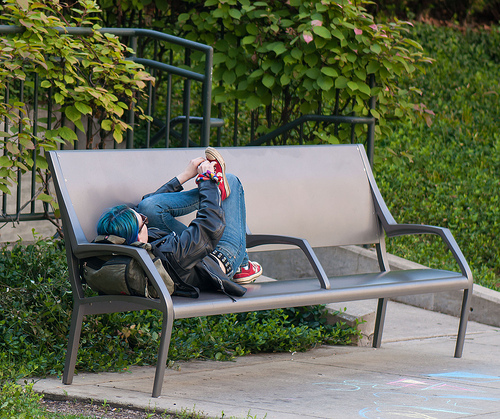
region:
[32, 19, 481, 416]
picture taken outside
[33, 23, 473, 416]
picture taken during the day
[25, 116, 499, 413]
a woman is laying on a bench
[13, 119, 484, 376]
the bench is on the sidewalk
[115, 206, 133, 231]
the woman's hair is blue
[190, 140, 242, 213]
the person is tying her shoes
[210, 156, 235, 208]
the woman wears red shoes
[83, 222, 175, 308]
the woman is laying on a backpack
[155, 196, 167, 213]
the woman wears jeans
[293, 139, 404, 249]
the bench is made of metal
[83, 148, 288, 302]
a girl lying on a metal bench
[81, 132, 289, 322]
this woman has blue hair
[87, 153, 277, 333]
her hair is dyed blue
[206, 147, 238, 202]
red Converse brand sneakers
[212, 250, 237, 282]
a black belt with a lot of holes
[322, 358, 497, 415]
colorful chalk on the ground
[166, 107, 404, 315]
there is a staircase behind the bench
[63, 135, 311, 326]
she is resting her head on her bag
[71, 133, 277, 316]
she is wearing a black leather jacket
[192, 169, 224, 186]
a brightly colored bracelet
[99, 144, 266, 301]
a girl lying on the bench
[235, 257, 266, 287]
the red sneaker on the bench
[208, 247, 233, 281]
the black belt with metal holes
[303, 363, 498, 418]
chalk drawings on the ground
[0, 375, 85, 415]
grass in the dirt patch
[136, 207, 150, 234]
glasses on the face of the women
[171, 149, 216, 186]
the girl ties her shoes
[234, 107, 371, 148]
the hand rail for the stairway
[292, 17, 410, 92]
pink tips on the green leaves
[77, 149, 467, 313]
a person laying on a bench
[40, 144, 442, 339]
a silver bench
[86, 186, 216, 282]
a person with blue and black hair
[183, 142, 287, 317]
red and white converse sneakers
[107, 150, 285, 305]
a person wearing blue jeans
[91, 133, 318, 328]
a person wearing converse sneakers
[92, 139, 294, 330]
a person wearing red and white converse sneakers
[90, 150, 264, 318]
a person wearing a black belt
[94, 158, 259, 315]
a person wearing a black jacket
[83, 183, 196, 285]
a person wearing sunglasses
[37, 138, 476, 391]
a girl lying on a metal bench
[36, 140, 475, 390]
a metal bench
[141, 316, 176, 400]
the leg of a metal bench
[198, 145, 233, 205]
a red and white tennis shoe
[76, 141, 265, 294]
a girl tying her shoe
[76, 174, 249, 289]
a girl wearing jeans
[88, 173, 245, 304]
a girl wearing a leather jacket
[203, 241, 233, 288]
a silver and black belt